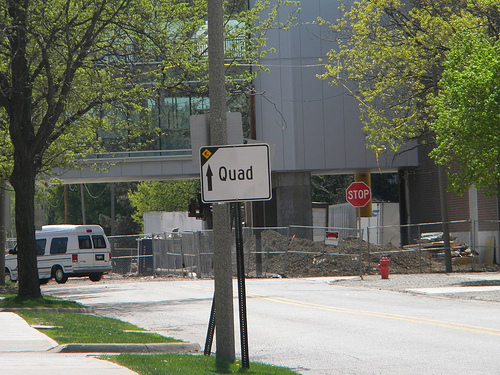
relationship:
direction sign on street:
[197, 142, 272, 373] [39, 274, 498, 372]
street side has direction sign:
[20, 271, 303, 375] [197, 142, 272, 373]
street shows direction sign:
[39, 274, 498, 372] [197, 142, 272, 373]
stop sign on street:
[345, 180, 374, 279] [39, 274, 498, 372]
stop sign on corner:
[345, 180, 374, 279] [286, 260, 376, 301]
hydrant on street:
[373, 248, 392, 282] [39, 274, 498, 372]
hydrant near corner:
[373, 248, 392, 282] [286, 260, 376, 301]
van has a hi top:
[2, 222, 117, 290] [39, 224, 104, 235]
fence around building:
[97, 218, 497, 275] [45, 8, 424, 241]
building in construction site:
[45, 8, 424, 241] [64, 189, 498, 280]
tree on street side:
[1, 1, 308, 298] [20, 271, 303, 375]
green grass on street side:
[0, 310, 183, 348] [20, 271, 303, 375]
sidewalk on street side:
[1, 312, 139, 375] [20, 271, 303, 375]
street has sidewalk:
[39, 274, 498, 372] [1, 312, 139, 375]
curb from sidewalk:
[51, 341, 205, 355] [1, 312, 139, 375]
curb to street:
[51, 341, 205, 355] [39, 274, 498, 372]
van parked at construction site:
[2, 222, 117, 290] [64, 189, 498, 280]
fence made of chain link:
[97, 218, 497, 275] [110, 237, 210, 278]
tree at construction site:
[314, 3, 499, 274] [64, 189, 498, 280]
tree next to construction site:
[314, 3, 499, 274] [64, 189, 498, 280]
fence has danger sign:
[97, 218, 497, 275] [323, 230, 341, 250]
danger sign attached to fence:
[323, 230, 341, 250] [97, 218, 497, 275]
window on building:
[107, 87, 189, 152] [45, 8, 424, 241]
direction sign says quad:
[197, 142, 272, 373] [217, 163, 255, 183]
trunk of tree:
[15, 187, 42, 306] [1, 1, 308, 298]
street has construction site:
[39, 274, 498, 372] [64, 189, 498, 280]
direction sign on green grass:
[197, 142, 272, 373] [0, 310, 183, 348]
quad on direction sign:
[217, 163, 255, 183] [197, 142, 272, 373]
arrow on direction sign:
[205, 164, 215, 195] [197, 142, 272, 373]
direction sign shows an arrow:
[197, 142, 272, 373] [205, 164, 215, 195]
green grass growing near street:
[0, 310, 183, 348] [39, 274, 498, 372]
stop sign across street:
[345, 180, 374, 279] [39, 274, 498, 372]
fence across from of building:
[97, 218, 497, 275] [45, 8, 424, 241]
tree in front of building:
[1, 1, 308, 298] [45, 8, 424, 241]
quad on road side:
[217, 163, 255, 183] [20, 271, 303, 375]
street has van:
[39, 274, 498, 372] [2, 222, 117, 290]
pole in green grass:
[208, 1, 235, 373] [0, 310, 183, 348]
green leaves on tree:
[316, 1, 499, 198] [1, 1, 308, 298]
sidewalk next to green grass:
[1, 312, 139, 375] [0, 310, 183, 348]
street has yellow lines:
[39, 274, 498, 372] [242, 295, 498, 340]